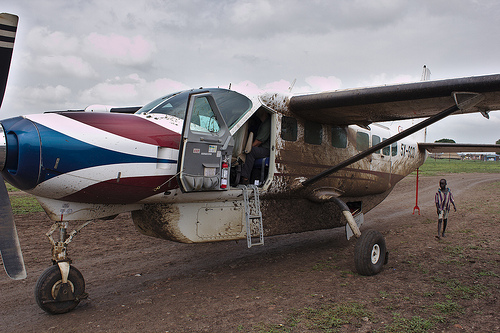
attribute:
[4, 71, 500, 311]
plane — muddy, blue, red, white, big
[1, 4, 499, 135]
sky — massive, cloudy, white, grey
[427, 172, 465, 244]
boy — walking , bare feet, standing, dark, brown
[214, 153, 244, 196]
extinguisher — red, can, fire